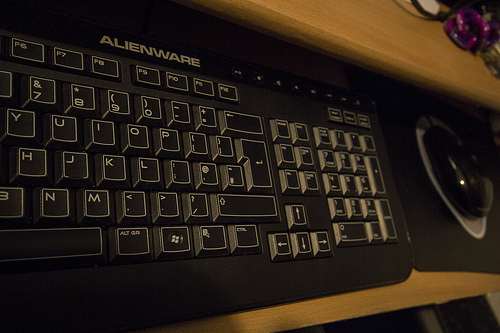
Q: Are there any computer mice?
A: Yes, there is a computer mouse.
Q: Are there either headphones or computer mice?
A: Yes, there is a computer mouse.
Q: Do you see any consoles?
A: No, there are no consoles.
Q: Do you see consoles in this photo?
A: No, there are no consoles.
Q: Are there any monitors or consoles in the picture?
A: No, there are no consoles or monitors.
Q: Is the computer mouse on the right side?
A: Yes, the computer mouse is on the right of the image.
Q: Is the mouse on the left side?
A: No, the mouse is on the right of the image.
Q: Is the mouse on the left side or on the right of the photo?
A: The mouse is on the right of the image.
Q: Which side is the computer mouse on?
A: The computer mouse is on the right of the image.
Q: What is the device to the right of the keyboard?
A: The device is a computer mouse.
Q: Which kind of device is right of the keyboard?
A: The device is a computer mouse.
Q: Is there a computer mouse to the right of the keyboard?
A: Yes, there is a computer mouse to the right of the keyboard.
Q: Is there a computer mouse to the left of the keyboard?
A: No, the computer mouse is to the right of the keyboard.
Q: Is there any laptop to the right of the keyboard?
A: No, there is a computer mouse to the right of the keyboard.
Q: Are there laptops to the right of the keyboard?
A: No, there is a computer mouse to the right of the keyboard.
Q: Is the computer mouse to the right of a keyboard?
A: Yes, the computer mouse is to the right of a keyboard.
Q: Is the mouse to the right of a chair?
A: No, the mouse is to the right of a keyboard.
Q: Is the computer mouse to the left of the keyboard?
A: No, the computer mouse is to the right of the keyboard.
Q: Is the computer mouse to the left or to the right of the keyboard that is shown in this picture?
A: The computer mouse is to the right of the keyboard.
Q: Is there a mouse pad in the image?
A: Yes, there is a mouse pad.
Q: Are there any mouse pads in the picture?
A: Yes, there is a mouse pad.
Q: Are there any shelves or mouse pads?
A: Yes, there is a mouse pad.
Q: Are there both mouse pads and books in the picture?
A: No, there is a mouse pad but no books.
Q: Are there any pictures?
A: No, there are no pictures.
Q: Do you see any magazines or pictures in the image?
A: No, there are no pictures or magazines.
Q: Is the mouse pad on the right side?
A: Yes, the mouse pad is on the right of the image.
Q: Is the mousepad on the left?
A: No, the mousepad is on the right of the image.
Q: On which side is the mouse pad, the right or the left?
A: The mouse pad is on the right of the image.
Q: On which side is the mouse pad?
A: The mouse pad is on the right of the image.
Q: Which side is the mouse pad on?
A: The mouse pad is on the right of the image.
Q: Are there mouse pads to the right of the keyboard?
A: Yes, there is a mouse pad to the right of the keyboard.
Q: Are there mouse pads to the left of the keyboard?
A: No, the mouse pad is to the right of the keyboard.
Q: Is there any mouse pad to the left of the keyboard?
A: No, the mouse pad is to the right of the keyboard.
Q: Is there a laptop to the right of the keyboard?
A: No, there is a mouse pad to the right of the keyboard.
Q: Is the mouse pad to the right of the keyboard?
A: Yes, the mouse pad is to the right of the keyboard.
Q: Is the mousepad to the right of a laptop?
A: No, the mousepad is to the right of the keyboard.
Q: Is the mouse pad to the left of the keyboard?
A: No, the mouse pad is to the right of the keyboard.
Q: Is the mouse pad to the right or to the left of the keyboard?
A: The mouse pad is to the right of the keyboard.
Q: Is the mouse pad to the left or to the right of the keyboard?
A: The mouse pad is to the right of the keyboard.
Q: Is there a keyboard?
A: Yes, there is a keyboard.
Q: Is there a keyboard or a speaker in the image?
A: Yes, there is a keyboard.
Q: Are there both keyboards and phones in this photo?
A: No, there is a keyboard but no phones.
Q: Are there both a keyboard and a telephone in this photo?
A: No, there is a keyboard but no phones.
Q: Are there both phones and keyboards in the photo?
A: No, there is a keyboard but no phones.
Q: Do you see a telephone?
A: No, there are no phones.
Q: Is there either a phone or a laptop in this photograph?
A: No, there are no phones or laptops.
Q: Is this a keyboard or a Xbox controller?
A: This is a keyboard.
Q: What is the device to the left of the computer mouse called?
A: The device is a keyboard.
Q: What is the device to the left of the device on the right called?
A: The device is a keyboard.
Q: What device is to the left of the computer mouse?
A: The device is a keyboard.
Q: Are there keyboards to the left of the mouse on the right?
A: Yes, there is a keyboard to the left of the mouse.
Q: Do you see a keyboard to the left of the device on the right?
A: Yes, there is a keyboard to the left of the mouse.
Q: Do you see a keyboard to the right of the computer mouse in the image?
A: No, the keyboard is to the left of the computer mouse.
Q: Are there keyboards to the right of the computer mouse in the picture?
A: No, the keyboard is to the left of the computer mouse.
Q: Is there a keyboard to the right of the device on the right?
A: No, the keyboard is to the left of the computer mouse.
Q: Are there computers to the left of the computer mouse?
A: No, there is a keyboard to the left of the computer mouse.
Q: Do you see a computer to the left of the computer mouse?
A: No, there is a keyboard to the left of the computer mouse.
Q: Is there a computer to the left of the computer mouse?
A: No, there is a keyboard to the left of the computer mouse.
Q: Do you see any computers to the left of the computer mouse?
A: No, there is a keyboard to the left of the computer mouse.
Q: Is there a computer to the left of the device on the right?
A: No, there is a keyboard to the left of the computer mouse.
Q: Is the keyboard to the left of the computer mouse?
A: Yes, the keyboard is to the left of the computer mouse.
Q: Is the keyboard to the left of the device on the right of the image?
A: Yes, the keyboard is to the left of the computer mouse.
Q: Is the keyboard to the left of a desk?
A: No, the keyboard is to the left of the computer mouse.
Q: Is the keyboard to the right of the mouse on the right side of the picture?
A: No, the keyboard is to the left of the computer mouse.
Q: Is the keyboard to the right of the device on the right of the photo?
A: No, the keyboard is to the left of the computer mouse.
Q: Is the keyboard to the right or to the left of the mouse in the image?
A: The keyboard is to the left of the mouse.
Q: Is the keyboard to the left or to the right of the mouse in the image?
A: The keyboard is to the left of the mouse.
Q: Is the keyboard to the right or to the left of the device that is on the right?
A: The keyboard is to the left of the mouse.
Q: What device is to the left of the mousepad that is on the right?
A: The device is a keyboard.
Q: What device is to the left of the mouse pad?
A: The device is a keyboard.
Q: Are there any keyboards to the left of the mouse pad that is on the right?
A: Yes, there is a keyboard to the left of the mousepad.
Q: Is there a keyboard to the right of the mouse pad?
A: No, the keyboard is to the left of the mouse pad.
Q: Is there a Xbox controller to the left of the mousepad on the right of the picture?
A: No, there is a keyboard to the left of the mousepad.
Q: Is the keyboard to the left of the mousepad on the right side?
A: Yes, the keyboard is to the left of the mousepad.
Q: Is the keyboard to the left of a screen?
A: No, the keyboard is to the left of the mousepad.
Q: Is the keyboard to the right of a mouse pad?
A: No, the keyboard is to the left of a mouse pad.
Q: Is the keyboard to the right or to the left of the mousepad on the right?
A: The keyboard is to the left of the mousepad.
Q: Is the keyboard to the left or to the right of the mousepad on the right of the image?
A: The keyboard is to the left of the mousepad.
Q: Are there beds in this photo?
A: No, there are no beds.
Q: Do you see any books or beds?
A: No, there are no beds or books.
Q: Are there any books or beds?
A: No, there are no beds or books.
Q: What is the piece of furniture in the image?
A: The piece of furniture is a shelf.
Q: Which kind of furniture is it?
A: The piece of furniture is a shelf.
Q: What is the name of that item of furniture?
A: This is a shelf.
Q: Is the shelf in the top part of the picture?
A: Yes, the shelf is in the top of the image.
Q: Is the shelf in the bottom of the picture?
A: No, the shelf is in the top of the image.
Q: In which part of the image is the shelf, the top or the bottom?
A: The shelf is in the top of the image.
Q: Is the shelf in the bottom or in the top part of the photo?
A: The shelf is in the top of the image.